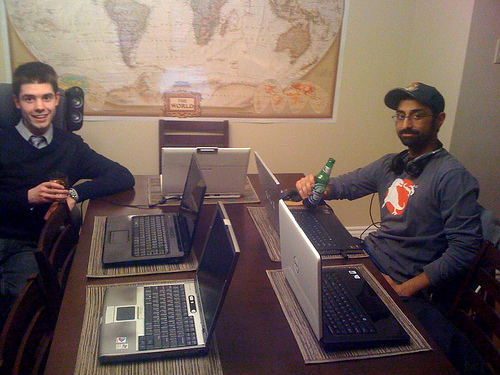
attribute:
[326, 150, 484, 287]
shirt — long, gray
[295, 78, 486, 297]
man — sitting, Young 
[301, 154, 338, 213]
beer bottle — green, Heinken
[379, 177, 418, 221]
dinosaur — white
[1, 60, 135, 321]
man — young, sitting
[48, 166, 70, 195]
glass — of liquor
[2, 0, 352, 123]
map — of the world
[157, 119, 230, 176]
chair — wooden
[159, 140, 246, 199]
laptop — silver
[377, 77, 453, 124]
cap — black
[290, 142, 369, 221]
beer bottle — green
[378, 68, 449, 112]
cap — baseball 